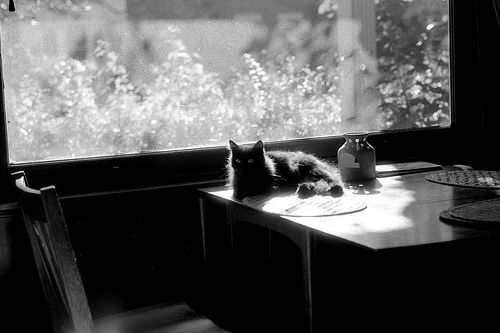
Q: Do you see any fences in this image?
A: No, there are no fences.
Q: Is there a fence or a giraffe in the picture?
A: No, there are no fences or giraffes.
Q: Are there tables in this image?
A: Yes, there is a table.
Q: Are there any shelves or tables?
A: Yes, there is a table.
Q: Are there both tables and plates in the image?
A: No, there is a table but no plates.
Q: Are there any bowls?
A: No, there are no bowls.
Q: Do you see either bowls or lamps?
A: No, there are no bowls or lamps.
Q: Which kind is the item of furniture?
A: The piece of furniture is a table.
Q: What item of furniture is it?
A: The piece of furniture is a table.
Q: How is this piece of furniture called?
A: This is a table.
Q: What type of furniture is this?
A: This is a table.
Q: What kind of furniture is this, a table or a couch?
A: This is a table.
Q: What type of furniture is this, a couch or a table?
A: This is a table.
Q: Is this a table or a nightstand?
A: This is a table.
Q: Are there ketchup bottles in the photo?
A: No, there are no ketchup bottles.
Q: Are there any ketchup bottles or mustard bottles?
A: No, there are no ketchup bottles or mustard bottles.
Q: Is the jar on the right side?
A: Yes, the jar is on the right of the image.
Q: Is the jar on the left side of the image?
A: No, the jar is on the right of the image.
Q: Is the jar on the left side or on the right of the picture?
A: The jar is on the right of the image.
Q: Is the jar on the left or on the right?
A: The jar is on the right of the image.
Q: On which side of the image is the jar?
A: The jar is on the right of the image.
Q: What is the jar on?
A: The jar is on the table.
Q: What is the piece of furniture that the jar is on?
A: The piece of furniture is a table.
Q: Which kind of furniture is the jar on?
A: The jar is on the table.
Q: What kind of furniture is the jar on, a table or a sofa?
A: The jar is on a table.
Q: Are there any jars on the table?
A: Yes, there is a jar on the table.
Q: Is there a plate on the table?
A: No, there is a jar on the table.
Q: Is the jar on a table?
A: Yes, the jar is on a table.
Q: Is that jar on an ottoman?
A: No, the jar is on a table.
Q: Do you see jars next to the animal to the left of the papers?
A: Yes, there is a jar next to the cat.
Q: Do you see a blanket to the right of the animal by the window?
A: No, there is a jar to the right of the cat.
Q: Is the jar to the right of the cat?
A: Yes, the jar is to the right of the cat.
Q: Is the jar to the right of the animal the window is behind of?
A: Yes, the jar is to the right of the cat.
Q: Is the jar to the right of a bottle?
A: No, the jar is to the right of the cat.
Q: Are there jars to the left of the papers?
A: Yes, there is a jar to the left of the papers.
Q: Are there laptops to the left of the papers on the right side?
A: No, there is a jar to the left of the papers.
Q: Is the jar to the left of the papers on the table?
A: Yes, the jar is to the left of the papers.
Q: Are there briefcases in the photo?
A: No, there are no briefcases.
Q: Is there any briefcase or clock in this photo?
A: No, there are no briefcases or clocks.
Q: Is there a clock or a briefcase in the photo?
A: No, there are no briefcases or clocks.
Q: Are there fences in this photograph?
A: No, there are no fences.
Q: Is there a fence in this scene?
A: No, there are no fences.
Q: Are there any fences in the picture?
A: No, there are no fences.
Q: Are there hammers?
A: No, there are no hammers.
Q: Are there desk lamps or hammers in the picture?
A: No, there are no hammers or desk lamps.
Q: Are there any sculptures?
A: No, there are no sculptures.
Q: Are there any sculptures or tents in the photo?
A: No, there are no sculptures or tents.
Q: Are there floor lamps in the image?
A: No, there are no floor lamps.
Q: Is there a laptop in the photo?
A: No, there are no laptops.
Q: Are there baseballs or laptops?
A: No, there are no laptops or baseballs.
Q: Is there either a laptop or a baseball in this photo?
A: No, there are no laptops or baseballs.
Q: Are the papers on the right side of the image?
A: Yes, the papers are on the right of the image.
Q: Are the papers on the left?
A: No, the papers are on the right of the image.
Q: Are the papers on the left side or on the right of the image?
A: The papers are on the right of the image.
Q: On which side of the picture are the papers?
A: The papers are on the right of the image.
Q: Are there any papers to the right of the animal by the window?
A: Yes, there are papers to the right of the cat.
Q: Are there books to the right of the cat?
A: No, there are papers to the right of the cat.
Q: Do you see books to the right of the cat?
A: No, there are papers to the right of the cat.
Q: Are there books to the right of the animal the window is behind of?
A: No, there are papers to the right of the cat.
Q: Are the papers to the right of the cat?
A: Yes, the papers are to the right of the cat.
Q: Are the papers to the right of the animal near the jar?
A: Yes, the papers are to the right of the cat.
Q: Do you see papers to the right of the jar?
A: Yes, there are papers to the right of the jar.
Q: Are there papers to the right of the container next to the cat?
A: Yes, there are papers to the right of the jar.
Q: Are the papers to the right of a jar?
A: Yes, the papers are to the right of a jar.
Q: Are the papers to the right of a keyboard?
A: No, the papers are to the right of a jar.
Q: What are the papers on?
A: The papers are on the table.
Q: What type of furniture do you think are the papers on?
A: The papers are on the table.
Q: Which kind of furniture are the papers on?
A: The papers are on the table.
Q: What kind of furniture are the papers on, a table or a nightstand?
A: The papers are on a table.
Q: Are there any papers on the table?
A: Yes, there are papers on the table.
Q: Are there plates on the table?
A: No, there are papers on the table.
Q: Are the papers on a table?
A: Yes, the papers are on a table.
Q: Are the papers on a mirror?
A: No, the papers are on a table.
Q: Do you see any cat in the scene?
A: Yes, there is a cat.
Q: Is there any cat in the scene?
A: Yes, there is a cat.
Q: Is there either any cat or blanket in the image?
A: Yes, there is a cat.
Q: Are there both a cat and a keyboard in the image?
A: No, there is a cat but no keyboards.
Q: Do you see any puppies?
A: No, there are no puppies.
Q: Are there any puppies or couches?
A: No, there are no puppies or couches.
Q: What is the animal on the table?
A: The animal is a cat.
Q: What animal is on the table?
A: The animal is a cat.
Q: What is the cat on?
A: The cat is on the table.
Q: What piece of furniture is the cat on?
A: The cat is on the table.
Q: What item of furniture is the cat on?
A: The cat is on the table.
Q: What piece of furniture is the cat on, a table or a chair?
A: The cat is on a table.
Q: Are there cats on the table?
A: Yes, there is a cat on the table.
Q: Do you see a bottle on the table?
A: No, there is a cat on the table.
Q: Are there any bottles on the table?
A: No, there is a cat on the table.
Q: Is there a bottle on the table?
A: No, there is a cat on the table.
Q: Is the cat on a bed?
A: No, the cat is on the table.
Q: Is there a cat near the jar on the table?
A: Yes, there is a cat near the jar.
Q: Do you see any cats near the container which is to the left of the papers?
A: Yes, there is a cat near the jar.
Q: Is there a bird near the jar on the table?
A: No, there is a cat near the jar.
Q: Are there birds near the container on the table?
A: No, there is a cat near the jar.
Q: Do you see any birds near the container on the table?
A: No, there is a cat near the jar.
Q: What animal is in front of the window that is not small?
A: The cat is in front of the window.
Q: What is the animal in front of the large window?
A: The animal is a cat.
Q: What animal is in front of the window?
A: The animal is a cat.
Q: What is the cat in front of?
A: The cat is in front of the window.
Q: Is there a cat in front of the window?
A: Yes, there is a cat in front of the window.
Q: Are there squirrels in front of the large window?
A: No, there is a cat in front of the window.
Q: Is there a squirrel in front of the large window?
A: No, there is a cat in front of the window.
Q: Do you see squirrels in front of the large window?
A: No, there is a cat in front of the window.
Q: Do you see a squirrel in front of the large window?
A: No, there is a cat in front of the window.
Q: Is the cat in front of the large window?
A: Yes, the cat is in front of the window.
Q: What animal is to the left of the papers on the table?
A: The animal is a cat.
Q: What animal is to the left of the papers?
A: The animal is a cat.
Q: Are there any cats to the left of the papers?
A: Yes, there is a cat to the left of the papers.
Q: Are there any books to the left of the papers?
A: No, there is a cat to the left of the papers.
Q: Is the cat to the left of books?
A: No, the cat is to the left of the papers.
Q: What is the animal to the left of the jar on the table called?
A: The animal is a cat.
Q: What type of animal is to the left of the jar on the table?
A: The animal is a cat.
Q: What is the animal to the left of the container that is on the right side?
A: The animal is a cat.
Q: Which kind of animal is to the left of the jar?
A: The animal is a cat.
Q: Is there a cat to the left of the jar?
A: Yes, there is a cat to the left of the jar.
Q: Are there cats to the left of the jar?
A: Yes, there is a cat to the left of the jar.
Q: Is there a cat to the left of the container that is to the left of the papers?
A: Yes, there is a cat to the left of the jar.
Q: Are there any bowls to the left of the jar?
A: No, there is a cat to the left of the jar.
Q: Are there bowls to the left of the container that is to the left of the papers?
A: No, there is a cat to the left of the jar.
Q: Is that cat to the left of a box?
A: No, the cat is to the left of a jar.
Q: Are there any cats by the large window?
A: Yes, there is a cat by the window.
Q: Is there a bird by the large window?
A: No, there is a cat by the window.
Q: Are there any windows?
A: Yes, there is a window.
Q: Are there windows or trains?
A: Yes, there is a window.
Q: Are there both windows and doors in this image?
A: No, there is a window but no doors.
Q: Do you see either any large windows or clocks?
A: Yes, there is a large window.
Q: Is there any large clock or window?
A: Yes, there is a large window.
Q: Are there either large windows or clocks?
A: Yes, there is a large window.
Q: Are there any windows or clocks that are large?
A: Yes, the window is large.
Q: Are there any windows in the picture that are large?
A: Yes, there is a large window.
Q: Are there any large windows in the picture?
A: Yes, there is a large window.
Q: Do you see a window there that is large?
A: Yes, there is a window that is large.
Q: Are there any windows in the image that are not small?
A: Yes, there is a large window.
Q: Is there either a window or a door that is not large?
A: No, there is a window but it is large.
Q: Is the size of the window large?
A: Yes, the window is large.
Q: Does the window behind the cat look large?
A: Yes, the window is large.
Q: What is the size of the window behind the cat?
A: The window is large.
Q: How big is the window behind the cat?
A: The window is large.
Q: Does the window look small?
A: No, the window is large.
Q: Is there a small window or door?
A: No, there is a window but it is large.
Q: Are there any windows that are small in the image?
A: No, there is a window but it is large.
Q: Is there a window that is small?
A: No, there is a window but it is large.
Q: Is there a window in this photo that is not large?
A: No, there is a window but it is large.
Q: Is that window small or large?
A: The window is large.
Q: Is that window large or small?
A: The window is large.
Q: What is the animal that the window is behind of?
A: The animal is a cat.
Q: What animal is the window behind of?
A: The window is behind the cat.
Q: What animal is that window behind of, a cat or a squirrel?
A: The window is behind a cat.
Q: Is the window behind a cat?
A: Yes, the window is behind a cat.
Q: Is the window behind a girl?
A: No, the window is behind a cat.